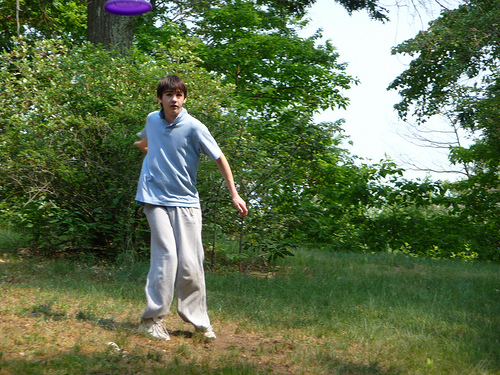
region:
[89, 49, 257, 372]
this is a person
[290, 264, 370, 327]
this is grass on the field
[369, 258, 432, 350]
this is grass on the field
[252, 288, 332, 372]
this is grass on the field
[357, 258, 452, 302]
this is grass on the field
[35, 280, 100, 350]
this is grass on the field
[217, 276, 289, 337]
this is grass on the field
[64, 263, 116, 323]
this is grass on the field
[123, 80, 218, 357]
A boy in the photo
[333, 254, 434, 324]
Grass in the photo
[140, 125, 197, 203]
Light blue t-shirt in the photo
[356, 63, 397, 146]
Clouds in the photo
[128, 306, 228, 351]
White shoes in the photo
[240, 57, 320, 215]
Tree leaves in the photo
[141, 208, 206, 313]
Gray pants in the photo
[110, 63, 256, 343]
A boy standing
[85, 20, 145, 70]
Tree trunk in the photo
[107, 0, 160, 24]
Purple frisbee in the photo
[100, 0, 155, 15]
Purple frisbee in the air.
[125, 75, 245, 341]
Boy on the grass.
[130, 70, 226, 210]
Blue shirt on the boy.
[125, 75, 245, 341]
Gray pants on the boy.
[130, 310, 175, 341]
White shoe on the foot.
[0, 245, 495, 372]
Grass on the ground.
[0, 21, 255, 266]
Bush behind the boy.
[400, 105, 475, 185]
Tree branches in the background.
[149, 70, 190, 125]
Brown hair on the boy.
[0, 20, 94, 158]
flowers on the bush.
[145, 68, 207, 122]
face of the person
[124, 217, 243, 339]
a boy wearing pant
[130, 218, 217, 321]
a young boy wearing lose pant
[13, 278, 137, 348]
shadow on the ground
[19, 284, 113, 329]
shadow of the boy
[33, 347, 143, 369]
shadow of the trees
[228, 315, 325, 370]
sun shine falling in ground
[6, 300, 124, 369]
sun light falling in ground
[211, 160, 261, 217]
hand of the boy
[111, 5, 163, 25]
a blue object in air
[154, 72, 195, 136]
the head of a boy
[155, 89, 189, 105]
the eyes of a boy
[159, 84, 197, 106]
the nose of a boy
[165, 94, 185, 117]
the mouth of a boy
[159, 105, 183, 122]
the chin of a boy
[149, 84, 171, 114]
the ear of a boy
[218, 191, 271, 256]
the hand of a boy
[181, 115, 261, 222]
the arm of a boy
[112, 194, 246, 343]
the legs of a boy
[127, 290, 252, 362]
the feet of a boy